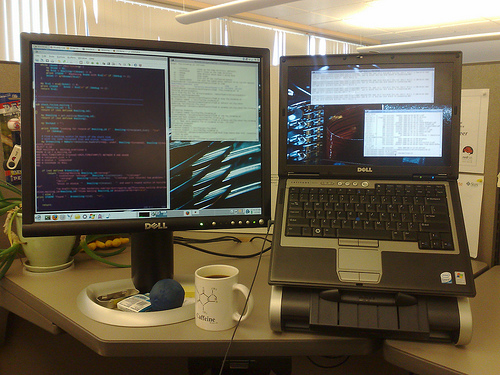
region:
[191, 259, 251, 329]
A coffee cup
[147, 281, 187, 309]
A blue ball under the monitor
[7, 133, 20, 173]
A flash drive in the monitor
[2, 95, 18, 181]
A pez dispenser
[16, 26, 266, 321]
A computer monitor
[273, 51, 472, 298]
A laptop computer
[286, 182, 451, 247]
a keyboard on the laptop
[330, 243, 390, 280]
the touch pad on the laptop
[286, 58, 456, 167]
monitor on the laptop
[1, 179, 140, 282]
A potted plant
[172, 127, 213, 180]
part of a monitor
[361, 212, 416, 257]
part of a keyboard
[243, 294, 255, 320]
part of a handle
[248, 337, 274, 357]
edge of a top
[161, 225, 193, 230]
edge of a screen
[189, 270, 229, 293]
edge of a cup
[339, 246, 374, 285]
part of a mouse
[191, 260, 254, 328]
A white coffee mug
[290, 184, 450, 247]
keyboard on the laptop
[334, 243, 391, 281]
touch pad on the laptop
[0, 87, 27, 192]
A pez dispenser in its packaging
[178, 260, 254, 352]
a white coffee cup on a desk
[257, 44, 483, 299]
a black laptop on desk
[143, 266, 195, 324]
a blue stress ball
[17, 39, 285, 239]
a black computer monitor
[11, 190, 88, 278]
a potted plant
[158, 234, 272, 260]
black wires on a desk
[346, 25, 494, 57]
a long floresent light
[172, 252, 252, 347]
a coffee cup filled with coffee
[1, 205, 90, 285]
a green plant pot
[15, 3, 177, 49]
vertical blinds covering a window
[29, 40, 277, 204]
this is a screen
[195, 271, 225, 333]
this is a cup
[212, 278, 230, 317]
the cup is white in color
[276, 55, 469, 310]
this is a laptop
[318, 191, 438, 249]
these are the buttons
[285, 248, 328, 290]
the laptop is black in color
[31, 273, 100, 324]
this is a table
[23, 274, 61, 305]
the table is wooden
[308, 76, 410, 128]
the screen is on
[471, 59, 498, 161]
this is the wall